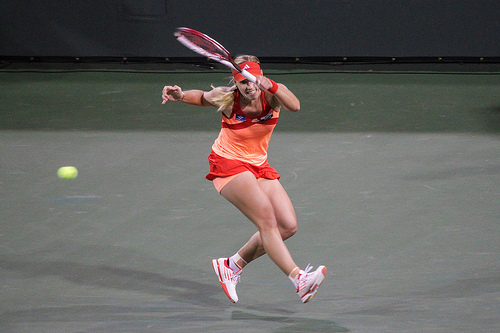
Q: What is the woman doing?
A: Playing tennis.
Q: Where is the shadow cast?
A: On the ground.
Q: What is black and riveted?
A: The game tarp.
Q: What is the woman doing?
A: Playing tennis.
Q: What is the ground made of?
A: Concrete.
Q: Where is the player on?
A: A tennis court.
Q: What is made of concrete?
A: The ground.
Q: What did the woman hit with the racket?
A: A tennis ball.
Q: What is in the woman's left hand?
A: A tennis racket.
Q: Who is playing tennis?
A: A woman.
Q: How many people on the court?
A: One.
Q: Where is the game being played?
A: Tennis court.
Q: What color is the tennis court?
A: Gray.